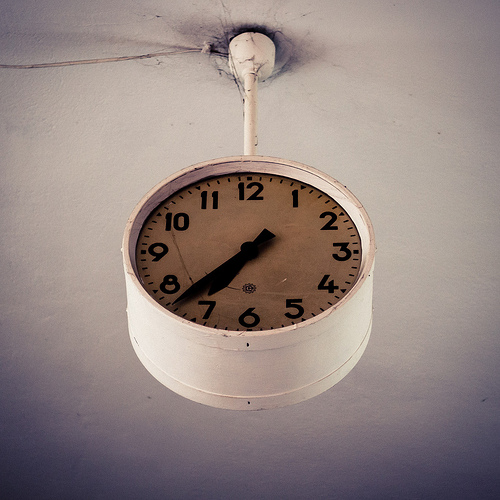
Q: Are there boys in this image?
A: No, there are no boys.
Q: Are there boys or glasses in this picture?
A: No, there are no boys or glasses.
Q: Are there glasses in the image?
A: No, there are no glasses.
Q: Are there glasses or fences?
A: No, there are no glasses or fences.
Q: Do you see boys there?
A: No, there are no boys.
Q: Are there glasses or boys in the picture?
A: No, there are no boys or glasses.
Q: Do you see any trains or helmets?
A: No, there are no helmets or trains.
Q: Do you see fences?
A: No, there are no fences.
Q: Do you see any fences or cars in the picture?
A: No, there are no fences or cars.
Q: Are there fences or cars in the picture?
A: No, there are no fences or cars.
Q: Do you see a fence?
A: No, there are no fences.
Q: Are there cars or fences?
A: No, there are no fences or cars.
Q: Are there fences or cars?
A: No, there are no fences or cars.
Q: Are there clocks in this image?
A: Yes, there is a clock.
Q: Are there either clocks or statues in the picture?
A: Yes, there is a clock.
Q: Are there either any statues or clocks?
A: Yes, there is a clock.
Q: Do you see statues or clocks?
A: Yes, there is a clock.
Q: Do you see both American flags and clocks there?
A: No, there is a clock but no American flags.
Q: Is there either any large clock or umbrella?
A: Yes, there is a large clock.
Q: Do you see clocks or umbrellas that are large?
A: Yes, the clock is large.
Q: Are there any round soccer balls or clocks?
A: Yes, there is a round clock.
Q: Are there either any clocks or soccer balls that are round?
A: Yes, the clock is round.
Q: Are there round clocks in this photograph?
A: Yes, there is a round clock.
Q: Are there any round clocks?
A: Yes, there is a round clock.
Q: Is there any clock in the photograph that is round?
A: Yes, there is a clock that is round.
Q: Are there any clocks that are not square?
A: Yes, there is a round clock.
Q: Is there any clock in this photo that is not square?
A: Yes, there is a round clock.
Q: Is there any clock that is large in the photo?
A: Yes, there is a large clock.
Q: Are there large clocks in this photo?
A: Yes, there is a large clock.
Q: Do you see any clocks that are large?
A: Yes, there is a clock that is large.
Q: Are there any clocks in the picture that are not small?
A: Yes, there is a large clock.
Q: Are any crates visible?
A: No, there are no crates.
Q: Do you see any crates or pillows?
A: No, there are no crates or pillows.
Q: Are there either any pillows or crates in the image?
A: No, there are no crates or pillows.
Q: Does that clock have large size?
A: Yes, the clock is large.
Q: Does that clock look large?
A: Yes, the clock is large.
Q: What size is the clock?
A: The clock is large.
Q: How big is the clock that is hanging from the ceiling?
A: The clock is large.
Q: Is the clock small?
A: No, the clock is large.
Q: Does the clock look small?
A: No, the clock is large.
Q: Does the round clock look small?
A: No, the clock is large.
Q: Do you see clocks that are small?
A: No, there is a clock but it is large.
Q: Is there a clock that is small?
A: No, there is a clock but it is large.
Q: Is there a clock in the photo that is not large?
A: No, there is a clock but it is large.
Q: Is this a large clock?
A: Yes, this is a large clock.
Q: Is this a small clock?
A: No, this is a large clock.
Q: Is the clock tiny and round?
A: No, the clock is round but large.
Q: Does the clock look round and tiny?
A: No, the clock is round but large.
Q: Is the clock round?
A: Yes, the clock is round.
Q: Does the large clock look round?
A: Yes, the clock is round.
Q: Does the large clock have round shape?
A: Yes, the clock is round.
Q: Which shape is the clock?
A: The clock is round.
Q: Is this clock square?
A: No, the clock is round.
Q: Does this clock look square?
A: No, the clock is round.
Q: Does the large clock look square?
A: No, the clock is round.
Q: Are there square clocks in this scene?
A: No, there is a clock but it is round.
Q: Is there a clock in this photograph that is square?
A: No, there is a clock but it is round.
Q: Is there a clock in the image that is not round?
A: No, there is a clock but it is round.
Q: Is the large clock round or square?
A: The clock is round.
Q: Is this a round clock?
A: Yes, this is a round clock.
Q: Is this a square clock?
A: No, this is a round clock.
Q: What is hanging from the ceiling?
A: The clock is hanging from the ceiling.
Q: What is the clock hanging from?
A: The clock is hanging from the ceiling.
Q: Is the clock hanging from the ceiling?
A: Yes, the clock is hanging from the ceiling.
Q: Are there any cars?
A: No, there are no cars.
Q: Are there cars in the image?
A: No, there are no cars.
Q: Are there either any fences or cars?
A: No, there are no cars or fences.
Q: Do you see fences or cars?
A: No, there are no cars or fences.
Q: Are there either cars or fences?
A: No, there are no cars or fences.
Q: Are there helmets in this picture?
A: No, there are no helmets.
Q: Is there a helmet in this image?
A: No, there are no helmets.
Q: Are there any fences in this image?
A: No, there are no fences.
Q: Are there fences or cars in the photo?
A: No, there are no fences or cars.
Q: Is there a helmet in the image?
A: No, there are no helmets.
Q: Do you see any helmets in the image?
A: No, there are no helmets.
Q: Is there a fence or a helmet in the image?
A: No, there are no helmets or fences.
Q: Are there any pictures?
A: No, there are no pictures.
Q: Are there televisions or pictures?
A: No, there are no pictures or televisions.